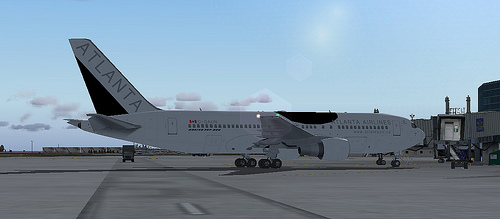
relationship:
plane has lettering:
[64, 37, 429, 172] [75, 40, 142, 113]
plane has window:
[64, 37, 429, 172] [186, 122, 192, 127]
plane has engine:
[64, 37, 429, 172] [296, 134, 353, 163]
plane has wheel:
[64, 37, 429, 172] [392, 158, 401, 167]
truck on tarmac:
[121, 143, 134, 162] [0, 154, 498, 217]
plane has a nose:
[64, 37, 429, 172] [411, 125, 429, 151]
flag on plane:
[187, 117, 201, 124] [64, 37, 429, 172]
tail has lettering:
[65, 37, 166, 149] [75, 40, 142, 113]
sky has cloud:
[0, 0, 499, 146] [7, 122, 53, 134]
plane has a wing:
[64, 37, 429, 172] [256, 113, 334, 159]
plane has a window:
[64, 37, 429, 172] [186, 122, 192, 127]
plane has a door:
[64, 37, 429, 172] [392, 119, 401, 139]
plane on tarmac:
[64, 37, 429, 172] [0, 154, 498, 217]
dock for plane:
[433, 109, 497, 152] [64, 37, 429, 172]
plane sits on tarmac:
[64, 37, 429, 172] [0, 154, 498, 217]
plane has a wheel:
[64, 37, 429, 172] [392, 158, 401, 167]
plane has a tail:
[64, 37, 429, 172] [65, 37, 166, 149]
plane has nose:
[64, 37, 429, 172] [411, 125, 429, 151]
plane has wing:
[64, 37, 429, 172] [256, 113, 334, 159]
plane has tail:
[64, 37, 429, 172] [65, 37, 166, 149]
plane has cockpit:
[64, 37, 429, 172] [406, 121, 424, 132]